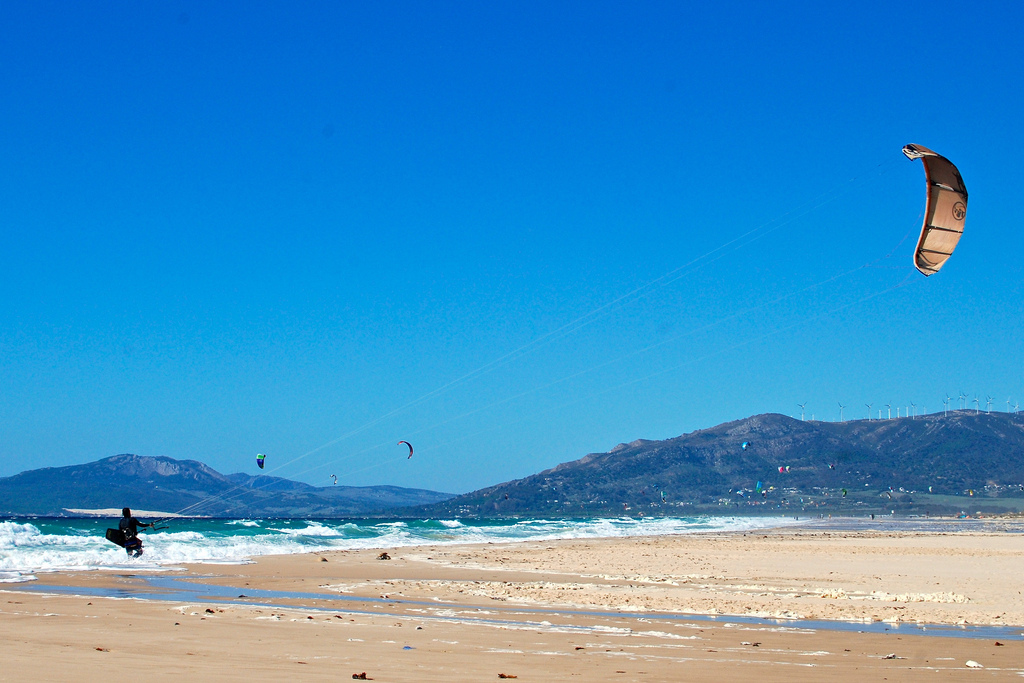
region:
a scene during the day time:
[9, 7, 1021, 665]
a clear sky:
[1, 4, 1017, 499]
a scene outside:
[9, 0, 1012, 671]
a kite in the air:
[873, 118, 988, 302]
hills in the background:
[7, 374, 1011, 558]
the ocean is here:
[3, 472, 870, 606]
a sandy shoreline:
[1, 486, 1017, 679]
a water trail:
[19, 567, 1007, 679]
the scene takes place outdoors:
[2, 3, 1020, 674]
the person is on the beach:
[110, 508, 146, 560]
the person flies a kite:
[900, 148, 964, 278]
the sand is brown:
[0, 521, 1012, 678]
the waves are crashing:
[0, 528, 816, 587]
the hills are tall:
[0, 424, 1019, 510]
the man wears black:
[106, 508, 148, 569]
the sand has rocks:
[0, 543, 1019, 680]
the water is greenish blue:
[3, 506, 803, 568]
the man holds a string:
[145, 208, 927, 531]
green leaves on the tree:
[576, 466, 619, 498]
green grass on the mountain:
[698, 419, 730, 443]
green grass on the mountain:
[809, 426, 825, 453]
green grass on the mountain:
[919, 425, 948, 448]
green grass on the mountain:
[987, 432, 1023, 470]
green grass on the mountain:
[944, 406, 1001, 479]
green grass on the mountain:
[111, 448, 188, 521]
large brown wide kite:
[903, 144, 974, 271]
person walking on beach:
[104, 505, 152, 548]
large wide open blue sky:
[0, 0, 1023, 487]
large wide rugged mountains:
[1, 450, 473, 515]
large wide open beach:
[0, 507, 1022, 681]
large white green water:
[0, 515, 822, 585]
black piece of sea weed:
[349, 669, 379, 680]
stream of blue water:
[688, 608, 1022, 643]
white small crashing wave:
[0, 518, 38, 532]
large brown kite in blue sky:
[908, 119, 982, 287]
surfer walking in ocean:
[101, 484, 158, 577]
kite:
[388, 417, 427, 474]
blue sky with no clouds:
[118, 104, 226, 223]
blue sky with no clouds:
[427, 256, 491, 291]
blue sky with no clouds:
[613, 157, 725, 275]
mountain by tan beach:
[135, 461, 241, 497]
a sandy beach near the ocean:
[339, 535, 891, 643]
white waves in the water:
[308, 509, 536, 566]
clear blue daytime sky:
[2, 2, 1020, 489]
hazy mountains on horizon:
[0, 451, 449, 512]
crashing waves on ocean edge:
[0, 514, 753, 571]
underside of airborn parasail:
[906, 147, 971, 275]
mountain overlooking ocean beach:
[396, 409, 1022, 543]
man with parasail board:
[106, 506, 158, 555]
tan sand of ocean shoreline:
[1, 527, 1020, 679]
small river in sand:
[8, 567, 1021, 679]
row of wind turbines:
[786, 393, 1020, 423]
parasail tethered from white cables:
[105, 144, 966, 555]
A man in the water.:
[84, 480, 183, 586]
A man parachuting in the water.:
[72, 478, 224, 565]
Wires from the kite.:
[189, 410, 421, 527]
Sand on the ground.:
[166, 547, 992, 680]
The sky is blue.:
[66, 136, 819, 383]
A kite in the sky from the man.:
[833, 135, 986, 285]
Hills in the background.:
[524, 374, 1022, 485]